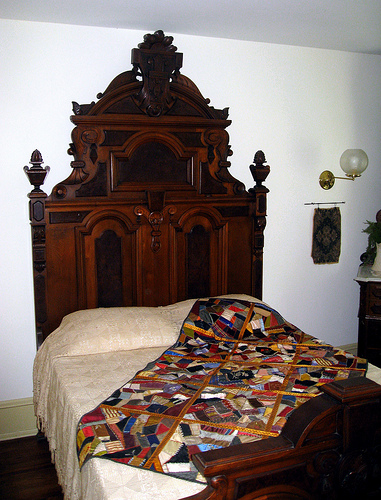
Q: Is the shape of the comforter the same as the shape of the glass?
A: No, the glass is round and the comforter is square.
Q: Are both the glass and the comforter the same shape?
A: No, the glass is round and the comforter is square.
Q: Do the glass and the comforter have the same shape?
A: No, the glass is round and the comforter is square.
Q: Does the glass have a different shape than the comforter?
A: Yes, the glass is round and the comforter is square.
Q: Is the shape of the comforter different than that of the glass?
A: Yes, the glass is round and the comforter is square.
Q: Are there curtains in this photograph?
A: No, there are no curtains.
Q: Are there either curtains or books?
A: No, there are no curtains or books.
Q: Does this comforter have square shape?
A: Yes, the comforter is square.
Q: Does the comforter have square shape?
A: Yes, the comforter is square.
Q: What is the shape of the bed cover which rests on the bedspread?
A: The comforter is square.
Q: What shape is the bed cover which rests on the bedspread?
A: The comforter is square.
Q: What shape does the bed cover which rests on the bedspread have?
A: The comforter has square shape.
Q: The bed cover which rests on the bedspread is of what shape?
A: The comforter is square.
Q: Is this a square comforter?
A: Yes, this is a square comforter.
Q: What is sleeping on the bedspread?
A: The quilt is sleeping on the bed spread.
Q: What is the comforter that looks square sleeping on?
A: The quilt is sleeping on the bedspread.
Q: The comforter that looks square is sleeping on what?
A: The quilt is sleeping on the bedspread.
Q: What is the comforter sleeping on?
A: The quilt is sleeping on the bedspread.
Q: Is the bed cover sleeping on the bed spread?
A: Yes, the bed cover is sleeping on the bed spread.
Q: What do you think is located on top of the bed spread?
A: The comforter is on top of the bed spread.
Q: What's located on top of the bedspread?
A: The comforter is on top of the bed spread.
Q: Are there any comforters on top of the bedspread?
A: Yes, there is a comforter on top of the bedspread.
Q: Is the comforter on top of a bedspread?
A: Yes, the comforter is on top of a bedspread.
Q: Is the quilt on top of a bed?
A: No, the quilt is on top of a bedspread.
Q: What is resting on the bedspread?
A: The comforter is resting on the bedspread.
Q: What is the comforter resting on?
A: The comforter is resting on the bed spread.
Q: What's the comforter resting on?
A: The comforter is resting on the bed spread.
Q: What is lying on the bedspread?
A: The comforter is lying on the bedspread.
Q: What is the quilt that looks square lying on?
A: The bed cover is lying on the bedspread.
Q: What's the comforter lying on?
A: The bed cover is lying on the bedspread.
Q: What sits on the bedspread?
A: The comforter sits on the bedspread.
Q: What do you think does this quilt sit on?
A: The quilt sits on the bedspread.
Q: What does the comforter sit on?
A: The quilt sits on the bedspread.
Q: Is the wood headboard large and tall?
A: Yes, the headboard is large and tall.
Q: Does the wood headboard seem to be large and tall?
A: Yes, the headboard is large and tall.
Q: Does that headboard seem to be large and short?
A: No, the headboard is large but tall.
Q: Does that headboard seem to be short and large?
A: No, the headboard is large but tall.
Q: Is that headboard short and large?
A: No, the headboard is large but tall.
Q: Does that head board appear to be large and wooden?
A: Yes, the head board is large and wooden.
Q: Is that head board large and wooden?
A: Yes, the head board is large and wooden.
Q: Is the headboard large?
A: Yes, the headboard is large.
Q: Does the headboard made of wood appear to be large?
A: Yes, the headboard is large.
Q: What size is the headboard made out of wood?
A: The headboard is large.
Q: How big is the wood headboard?
A: The headboard is large.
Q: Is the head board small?
A: No, the head board is large.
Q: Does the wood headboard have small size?
A: No, the head board is large.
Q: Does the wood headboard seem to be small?
A: No, the head board is large.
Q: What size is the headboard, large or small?
A: The headboard is large.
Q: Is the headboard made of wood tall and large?
A: Yes, the headboard is tall and large.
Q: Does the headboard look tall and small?
A: No, the headboard is tall but large.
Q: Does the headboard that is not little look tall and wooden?
A: Yes, the headboard is tall and wooden.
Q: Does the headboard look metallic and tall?
A: No, the headboard is tall but wooden.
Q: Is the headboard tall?
A: Yes, the headboard is tall.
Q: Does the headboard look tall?
A: Yes, the headboard is tall.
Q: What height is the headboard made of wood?
A: The headboard is tall.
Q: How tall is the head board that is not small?
A: The headboard is tall.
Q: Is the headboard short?
A: No, the headboard is tall.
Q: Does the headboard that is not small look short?
A: No, the head board is tall.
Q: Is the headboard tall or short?
A: The headboard is tall.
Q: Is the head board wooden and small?
A: No, the head board is wooden but large.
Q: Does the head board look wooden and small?
A: No, the head board is wooden but large.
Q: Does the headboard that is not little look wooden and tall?
A: Yes, the headboard is wooden and tall.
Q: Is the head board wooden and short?
A: No, the head board is wooden but tall.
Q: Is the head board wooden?
A: Yes, the head board is wooden.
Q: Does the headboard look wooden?
A: Yes, the headboard is wooden.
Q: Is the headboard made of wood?
A: Yes, the headboard is made of wood.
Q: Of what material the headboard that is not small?
A: The headboard is made of wood.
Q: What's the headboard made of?
A: The headboard is made of wood.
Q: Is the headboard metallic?
A: No, the headboard is wooden.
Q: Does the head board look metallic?
A: No, the head board is wooden.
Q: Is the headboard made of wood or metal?
A: The headboard is made of wood.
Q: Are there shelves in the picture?
A: No, there are no shelves.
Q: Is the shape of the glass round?
A: Yes, the glass is round.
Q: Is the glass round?
A: Yes, the glass is round.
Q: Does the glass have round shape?
A: Yes, the glass is round.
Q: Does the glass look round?
A: Yes, the glass is round.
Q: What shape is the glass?
A: The glass is round.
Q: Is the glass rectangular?
A: No, the glass is round.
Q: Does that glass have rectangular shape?
A: No, the glass is round.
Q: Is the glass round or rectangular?
A: The glass is round.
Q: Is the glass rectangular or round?
A: The glass is round.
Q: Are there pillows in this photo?
A: Yes, there is a pillow.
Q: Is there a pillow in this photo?
A: Yes, there is a pillow.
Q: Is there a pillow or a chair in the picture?
A: Yes, there is a pillow.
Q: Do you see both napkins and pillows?
A: No, there is a pillow but no napkins.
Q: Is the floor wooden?
A: Yes, the floor is wooden.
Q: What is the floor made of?
A: The floor is made of wood.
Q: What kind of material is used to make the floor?
A: The floor is made of wood.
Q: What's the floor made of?
A: The floor is made of wood.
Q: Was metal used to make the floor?
A: No, the floor is made of wood.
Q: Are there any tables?
A: Yes, there is a table.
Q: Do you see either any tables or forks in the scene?
A: Yes, there is a table.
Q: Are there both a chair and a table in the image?
A: No, there is a table but no chairs.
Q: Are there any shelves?
A: No, there are no shelves.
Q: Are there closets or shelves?
A: No, there are no shelves or closets.